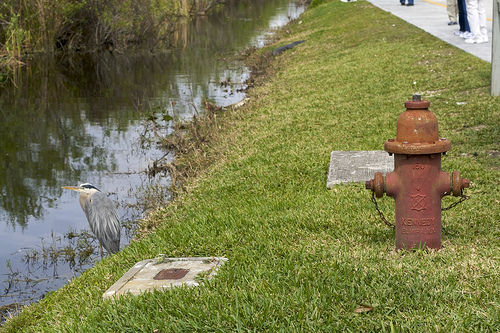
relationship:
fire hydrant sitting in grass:
[364, 91, 472, 257] [4, 2, 498, 330]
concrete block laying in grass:
[102, 256, 227, 296] [4, 2, 498, 330]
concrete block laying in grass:
[323, 147, 400, 193] [4, 2, 498, 330]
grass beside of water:
[4, 2, 498, 330] [0, 1, 306, 317]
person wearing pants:
[465, 1, 494, 46] [466, 2, 493, 47]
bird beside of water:
[59, 178, 122, 277] [0, 1, 306, 317]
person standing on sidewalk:
[465, 1, 494, 46] [370, 1, 494, 63]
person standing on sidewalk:
[454, 1, 472, 47] [370, 1, 494, 63]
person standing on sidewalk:
[444, 0, 461, 31] [370, 1, 494, 63]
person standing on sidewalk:
[399, 0, 420, 9] [370, 1, 494, 63]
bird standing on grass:
[59, 178, 122, 277] [4, 2, 498, 330]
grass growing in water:
[4, 2, 499, 333] [0, 1, 306, 317]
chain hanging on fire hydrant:
[368, 192, 394, 234] [364, 91, 472, 257]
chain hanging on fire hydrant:
[442, 195, 470, 213] [364, 91, 472, 257]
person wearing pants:
[454, 1, 472, 47] [455, 2, 469, 40]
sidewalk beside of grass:
[370, 1, 494, 63] [4, 2, 498, 330]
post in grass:
[489, 1, 499, 99] [4, 2, 498, 330]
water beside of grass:
[0, 1, 306, 317] [4, 2, 498, 330]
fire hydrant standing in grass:
[364, 91, 472, 257] [4, 2, 498, 330]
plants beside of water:
[4, 1, 148, 73] [0, 1, 306, 317]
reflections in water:
[5, 1, 295, 236] [0, 1, 306, 317]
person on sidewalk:
[465, 1, 494, 46] [370, 1, 494, 63]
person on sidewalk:
[454, 1, 472, 47] [370, 1, 494, 63]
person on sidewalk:
[444, 0, 461, 31] [370, 1, 494, 63]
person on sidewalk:
[399, 0, 420, 9] [370, 1, 494, 63]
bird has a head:
[59, 178, 122, 277] [64, 181, 103, 198]